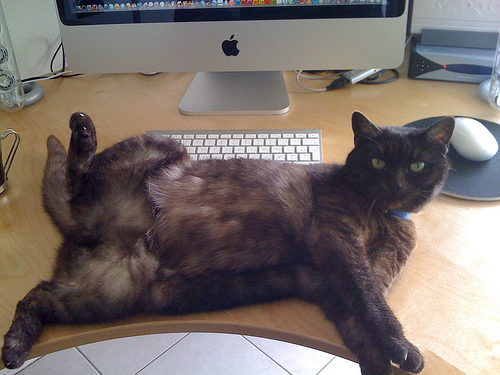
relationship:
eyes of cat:
[372, 154, 426, 175] [3, 111, 458, 373]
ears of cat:
[351, 109, 457, 149] [3, 111, 458, 373]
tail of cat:
[38, 133, 74, 232] [3, 111, 458, 373]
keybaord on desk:
[144, 125, 325, 172] [2, 45, 499, 373]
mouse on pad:
[448, 117, 500, 161] [400, 117, 499, 203]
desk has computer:
[2, 45, 499, 373] [53, 0, 413, 76]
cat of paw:
[3, 111, 458, 373] [386, 334, 424, 374]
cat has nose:
[3, 111, 458, 373] [386, 176, 401, 189]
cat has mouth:
[3, 111, 458, 373] [384, 189, 410, 208]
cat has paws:
[3, 111, 458, 373] [358, 332, 428, 373]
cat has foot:
[3, 111, 458, 373] [67, 106, 97, 198]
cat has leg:
[3, 111, 458, 373] [1, 276, 106, 373]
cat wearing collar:
[3, 111, 458, 373] [376, 200, 412, 222]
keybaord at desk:
[144, 125, 325, 172] [2, 45, 499, 373]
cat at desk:
[3, 111, 458, 373] [2, 45, 499, 373]